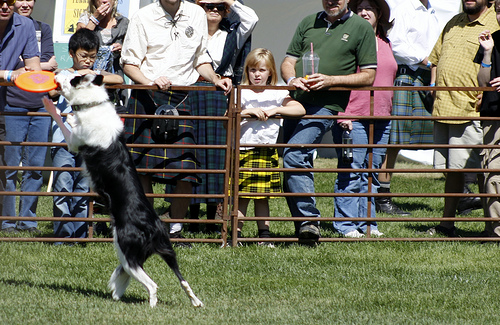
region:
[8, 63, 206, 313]
black and white dog catches a frisbee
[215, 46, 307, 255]
a small blonde girl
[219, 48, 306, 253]
young girl wears a plaid skirt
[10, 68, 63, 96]
an orange frisbee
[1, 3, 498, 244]
people stand behind a fence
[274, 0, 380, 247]
a man is leaning on a fence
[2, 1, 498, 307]
spectators are watching a dog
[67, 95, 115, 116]
collar around a dog's neck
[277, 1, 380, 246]
man is holding a clear plastic cup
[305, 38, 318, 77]
red straw inside a plastic cup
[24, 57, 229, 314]
a black and white dog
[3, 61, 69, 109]
an orange round frisbee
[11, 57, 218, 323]
a dog catching frisbee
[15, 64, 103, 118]
frisbee in mouth of dog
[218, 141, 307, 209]
a yellow and black skirt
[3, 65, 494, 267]
a brown metal fence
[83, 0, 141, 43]
a hand over the mouth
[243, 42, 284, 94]
blond hair on little girl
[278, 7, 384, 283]
a man in green shirt an blue jeans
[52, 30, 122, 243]
kid near the fence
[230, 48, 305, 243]
girl is watching dog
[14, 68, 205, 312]
dog with a frisbee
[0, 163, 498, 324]
grass covers the ground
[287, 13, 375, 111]
the shirt is green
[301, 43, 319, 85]
cup is almost empty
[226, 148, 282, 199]
skirt is yellow and black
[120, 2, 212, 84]
the shirt is white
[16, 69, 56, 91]
the frisbee is orange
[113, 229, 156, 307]
leg of a dog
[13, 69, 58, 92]
An orange frisbee with pink decal on the center.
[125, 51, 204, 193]
Man wearing a Scottish plaid kilt.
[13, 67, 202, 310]
Black and white dog jumping to catch and orange frisbee.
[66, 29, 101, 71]
Boy with black hair and glasses.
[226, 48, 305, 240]
Young girl with red hair wearing a yellow kilt.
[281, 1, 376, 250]
Older man wearing a green polo shirt and blue jeans leaning on a fence.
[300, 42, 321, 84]
A nearly empty disposable plastic cup with pink straw.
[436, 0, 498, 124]
Man with beard wearing yellow shirt.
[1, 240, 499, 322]
Slightly yellowing green grass.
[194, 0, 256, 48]
Woman shading her eyes with her hand from the sun.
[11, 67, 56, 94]
a pink and orange frisbee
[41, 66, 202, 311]
a black and white dog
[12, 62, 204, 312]
dog holding a frisbee in his mouth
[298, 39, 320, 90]
cup with a straw in man's hand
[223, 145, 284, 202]
yellow and black checkered skirt on girl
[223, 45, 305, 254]
blonde girl behind the fence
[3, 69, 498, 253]
a brown fence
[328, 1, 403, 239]
woman in pink shirt standing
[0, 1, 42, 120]
guy in blue shirt and sunglasses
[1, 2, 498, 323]
people watching a dog catching a frisbee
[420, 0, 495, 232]
a person is standing up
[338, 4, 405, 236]
a person is standing up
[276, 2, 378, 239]
a person is standing up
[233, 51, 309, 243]
a person is standing up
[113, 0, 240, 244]
a person is standing up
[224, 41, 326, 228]
a person watching the dog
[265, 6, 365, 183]
a person watching the dog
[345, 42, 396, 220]
a person watching the dog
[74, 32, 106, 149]
a person watching the dog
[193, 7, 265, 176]
a person watching the dog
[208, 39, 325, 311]
a person watching the dog